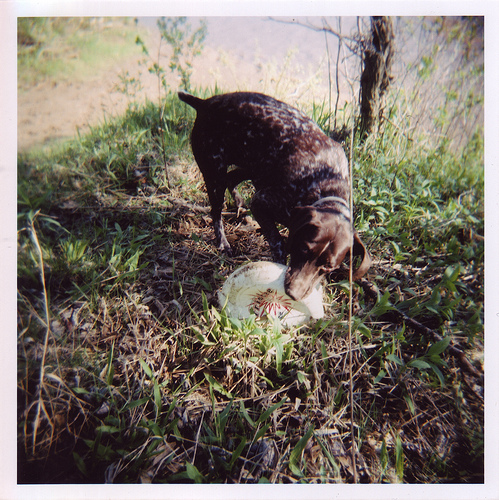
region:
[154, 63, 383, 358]
a dog playing with an object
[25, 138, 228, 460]
discolored grass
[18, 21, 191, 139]
a lonely road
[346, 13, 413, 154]
a stem of a dry tree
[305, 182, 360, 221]
white dog collar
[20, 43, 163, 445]
dry and arid land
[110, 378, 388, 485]
branch of green leaves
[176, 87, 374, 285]
a brown dog playing around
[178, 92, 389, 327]
dog biting a white object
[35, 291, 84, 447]
some dead branches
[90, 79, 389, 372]
A frisbee in the dog's mouth.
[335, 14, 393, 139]
The trunk of the tree.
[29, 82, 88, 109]
Dirt on the ground.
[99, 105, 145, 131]
The grass is green.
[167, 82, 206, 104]
The dog has a stub tail.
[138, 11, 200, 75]
A small green plant.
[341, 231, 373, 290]
The dog has a floppy ear.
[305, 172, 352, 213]
The dog is wearing a collar.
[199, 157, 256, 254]
The dog has two back legs.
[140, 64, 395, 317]
Dog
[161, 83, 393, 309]
Fur is white and brown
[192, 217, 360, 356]
Dog is carrying an item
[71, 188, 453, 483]
Grass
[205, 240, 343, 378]
Object is white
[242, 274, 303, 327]
A logo on the object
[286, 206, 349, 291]
Dog is looking upward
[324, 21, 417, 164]
Tree in the back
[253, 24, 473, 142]
Water to the side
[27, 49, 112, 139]
No grass there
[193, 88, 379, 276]
A brown dog in the grass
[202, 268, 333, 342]
A white fribbie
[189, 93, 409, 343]
A dog grabbing a fribbie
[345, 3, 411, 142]
A tree behind the dog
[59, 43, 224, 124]
A path behind the dog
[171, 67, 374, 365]
A dog playing with a fribbie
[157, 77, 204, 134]
The tail of the dog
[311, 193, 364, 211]
A brown collar on the dog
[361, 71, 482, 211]
Tall weeds beside the dog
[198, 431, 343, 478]
A rock in front of the dog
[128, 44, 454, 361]
a dog outside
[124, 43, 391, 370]
a dog is outside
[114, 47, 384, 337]
a dog with a short tail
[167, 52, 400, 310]
a dog with a collar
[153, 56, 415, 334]
a dog with floppy ears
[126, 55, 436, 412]
a dog walking in a grass area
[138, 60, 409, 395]
a dgo picking up a freesbee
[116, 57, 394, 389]
a dog picking up a dirty freesbee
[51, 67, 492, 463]
an area with grass and sticks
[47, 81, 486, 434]
a field of grass and sticks